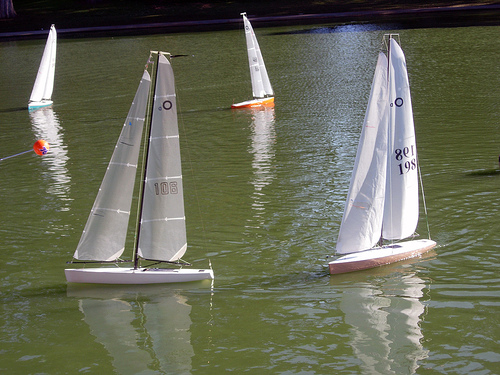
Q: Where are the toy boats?
A: In the water.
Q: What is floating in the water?
A: Toy sailboats.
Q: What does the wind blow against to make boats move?
A: Sails.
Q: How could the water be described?
A: Murky.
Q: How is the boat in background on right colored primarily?
A: Orange.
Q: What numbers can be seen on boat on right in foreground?
A: 801195.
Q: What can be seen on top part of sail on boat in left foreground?
A: Circle.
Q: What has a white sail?
A: Toy boats.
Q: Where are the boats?
A: On water.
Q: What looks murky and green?
A: Water.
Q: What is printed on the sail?
A: Numbers.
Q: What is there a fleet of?
A: Toy boats.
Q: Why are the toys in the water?
A: Competition.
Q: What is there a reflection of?
A: Boats.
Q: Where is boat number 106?
A: On left.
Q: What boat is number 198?
A: Pink boat.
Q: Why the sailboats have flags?
A: For the winds.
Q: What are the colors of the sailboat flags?
A: White.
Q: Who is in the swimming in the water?
A: No one.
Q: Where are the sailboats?
A: On the water.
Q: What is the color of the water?
A: Green.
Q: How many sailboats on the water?
A: Four.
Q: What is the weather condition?
A: Sunny.